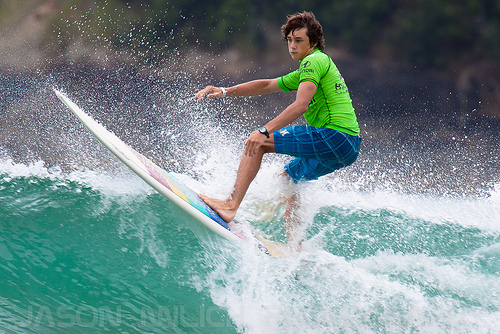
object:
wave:
[0, 156, 500, 334]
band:
[219, 86, 226, 98]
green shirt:
[277, 48, 360, 136]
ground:
[407, 135, 437, 157]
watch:
[258, 127, 270, 139]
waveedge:
[0, 157, 499, 232]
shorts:
[273, 125, 363, 184]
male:
[194, 10, 362, 251]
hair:
[281, 10, 326, 51]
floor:
[359, 148, 410, 190]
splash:
[0, 107, 500, 334]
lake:
[0, 161, 500, 334]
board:
[54, 89, 287, 260]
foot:
[197, 193, 235, 223]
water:
[0, 163, 500, 334]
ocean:
[0, 159, 500, 333]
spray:
[375, 128, 487, 197]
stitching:
[319, 60, 331, 90]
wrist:
[223, 88, 232, 97]